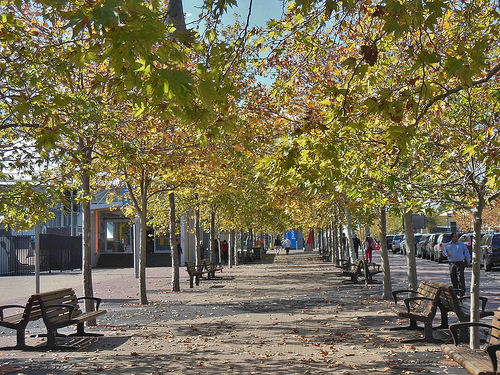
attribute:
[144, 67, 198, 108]
leaf — large, brown, green, yellow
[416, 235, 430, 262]
car — parked, in a line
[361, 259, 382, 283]
bench — brown, attached, black, in a row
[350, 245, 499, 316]
road — gray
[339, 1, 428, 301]
tree — in a group, skinny, slender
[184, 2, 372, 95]
sky — blue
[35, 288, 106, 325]
wood — brown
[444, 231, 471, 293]
man — walking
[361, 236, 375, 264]
woman — walking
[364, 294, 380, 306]
leaf — dead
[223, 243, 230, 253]
shirt — red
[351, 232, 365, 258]
man — wearing black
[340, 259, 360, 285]
bench — black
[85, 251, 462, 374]
pavement — gray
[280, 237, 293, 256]
person — walking